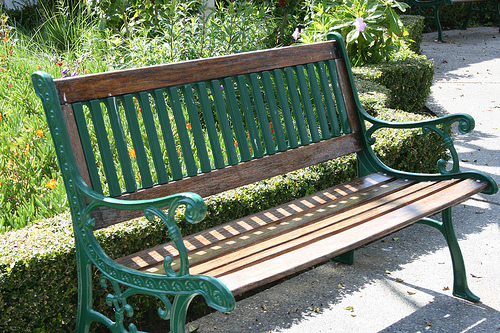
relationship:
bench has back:
[67, 34, 344, 288] [137, 66, 375, 196]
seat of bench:
[216, 173, 352, 253] [67, 34, 344, 288]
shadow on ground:
[378, 256, 474, 329] [266, 291, 379, 324]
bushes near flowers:
[19, 25, 182, 88] [9, 122, 46, 163]